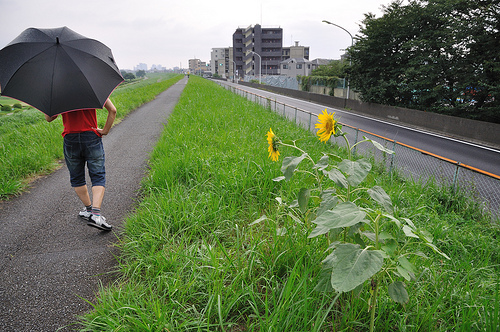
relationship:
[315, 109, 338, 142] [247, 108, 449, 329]
sunflower on plant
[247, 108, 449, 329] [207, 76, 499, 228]
plant on side of road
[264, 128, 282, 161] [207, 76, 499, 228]
sunflower on side of road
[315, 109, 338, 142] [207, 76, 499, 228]
sunflower on side of road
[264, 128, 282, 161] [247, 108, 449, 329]
sunflower on plant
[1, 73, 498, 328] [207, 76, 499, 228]
grass on side of road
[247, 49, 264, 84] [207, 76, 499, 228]
street light along road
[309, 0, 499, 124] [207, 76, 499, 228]
trees along road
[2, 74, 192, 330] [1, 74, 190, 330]
asphalt on path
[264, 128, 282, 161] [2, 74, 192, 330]
sunflower growing on side of asphalt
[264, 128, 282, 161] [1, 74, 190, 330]
sunflower growing on side of path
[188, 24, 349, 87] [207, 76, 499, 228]
buildings next to road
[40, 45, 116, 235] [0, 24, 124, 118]
man walking with umbrella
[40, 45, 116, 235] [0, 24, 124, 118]
man walking with an umbrella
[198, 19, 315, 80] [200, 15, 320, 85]
group of building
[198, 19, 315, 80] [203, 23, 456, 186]
group on right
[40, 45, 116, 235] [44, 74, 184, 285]
man walking down a path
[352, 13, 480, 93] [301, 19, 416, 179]
top on side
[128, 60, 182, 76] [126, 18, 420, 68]
skyline far off on horizon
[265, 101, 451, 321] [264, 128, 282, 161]
plant with sunflower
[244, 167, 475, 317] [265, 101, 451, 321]
leaves of a plant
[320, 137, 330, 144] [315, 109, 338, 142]
petals of a sunflower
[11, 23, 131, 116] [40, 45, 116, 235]
umbrella open above a man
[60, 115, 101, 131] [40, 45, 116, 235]
shirt on man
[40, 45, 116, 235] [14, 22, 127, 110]
man with umbrella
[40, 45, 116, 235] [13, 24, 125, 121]
man with umbrella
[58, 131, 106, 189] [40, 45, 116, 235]
jean on man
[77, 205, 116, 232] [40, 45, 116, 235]
shoes on man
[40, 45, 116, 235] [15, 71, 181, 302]
man walking down path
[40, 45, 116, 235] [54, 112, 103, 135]
man dressed in t-shirt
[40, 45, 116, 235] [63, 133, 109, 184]
man dressed in jeans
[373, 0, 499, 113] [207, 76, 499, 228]
trees growing next to road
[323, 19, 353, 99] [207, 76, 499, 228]
lamp post hanging over road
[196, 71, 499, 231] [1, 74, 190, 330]
fence along path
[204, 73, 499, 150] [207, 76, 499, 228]
guard along road